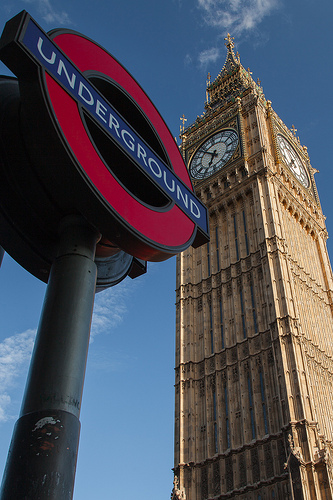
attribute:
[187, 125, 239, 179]
clock — black, white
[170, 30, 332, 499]
tower — large, tan